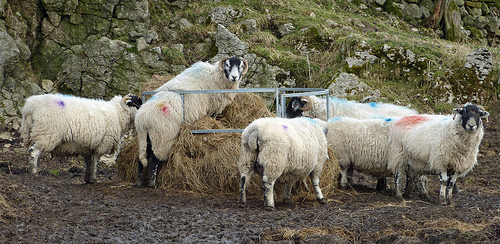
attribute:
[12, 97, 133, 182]
sheep — white, standing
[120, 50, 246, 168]
sheep — white, standing, whtie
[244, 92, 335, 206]
sheep — white, standing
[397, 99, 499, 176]
sheep — white, standing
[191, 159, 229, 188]
hay — tan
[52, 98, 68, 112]
dot — purple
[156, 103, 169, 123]
dot — red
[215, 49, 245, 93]
face — black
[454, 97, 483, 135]
face — black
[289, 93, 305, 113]
face — black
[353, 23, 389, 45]
grass — gree